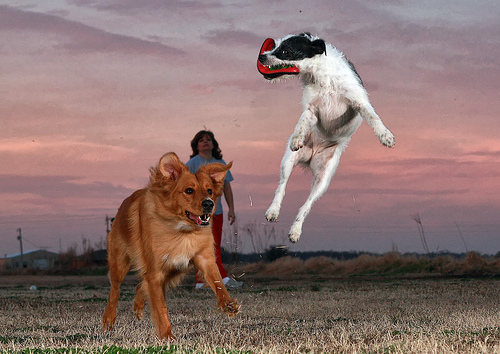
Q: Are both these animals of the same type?
A: Yes, all the animals are dogs.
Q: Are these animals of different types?
A: No, all the animals are dogs.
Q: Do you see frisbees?
A: Yes, there is a frisbee.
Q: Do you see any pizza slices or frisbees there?
A: Yes, there is a frisbee.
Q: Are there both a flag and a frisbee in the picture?
A: No, there is a frisbee but no flags.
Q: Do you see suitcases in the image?
A: No, there are no suitcases.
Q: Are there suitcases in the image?
A: No, there are no suitcases.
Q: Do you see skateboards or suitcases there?
A: No, there are no suitcases or skateboards.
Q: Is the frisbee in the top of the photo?
A: Yes, the frisbee is in the top of the image.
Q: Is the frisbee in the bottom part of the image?
A: No, the frisbee is in the top of the image.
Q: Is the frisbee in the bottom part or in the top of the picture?
A: The frisbee is in the top of the image.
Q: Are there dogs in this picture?
A: Yes, there is a dog.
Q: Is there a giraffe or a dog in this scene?
A: Yes, there is a dog.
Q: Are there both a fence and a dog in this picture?
A: No, there is a dog but no fences.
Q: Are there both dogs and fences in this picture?
A: No, there is a dog but no fences.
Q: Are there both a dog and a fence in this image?
A: No, there is a dog but no fences.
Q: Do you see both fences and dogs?
A: No, there is a dog but no fences.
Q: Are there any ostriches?
A: No, there are no ostriches.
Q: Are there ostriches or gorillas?
A: No, there are no ostriches or gorillas.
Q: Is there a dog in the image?
A: Yes, there is a dog.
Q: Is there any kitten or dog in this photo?
A: Yes, there is a dog.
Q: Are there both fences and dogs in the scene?
A: No, there is a dog but no fences.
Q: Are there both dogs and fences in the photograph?
A: No, there is a dog but no fences.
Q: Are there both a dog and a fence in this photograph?
A: No, there is a dog but no fences.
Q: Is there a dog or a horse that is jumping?
A: Yes, the dog is jumping.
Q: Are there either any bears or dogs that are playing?
A: Yes, the dog is playing.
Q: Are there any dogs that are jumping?
A: Yes, there is a dog that is jumping.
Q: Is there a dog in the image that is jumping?
A: Yes, there is a dog that is jumping.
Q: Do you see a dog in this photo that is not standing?
A: Yes, there is a dog that is jumping .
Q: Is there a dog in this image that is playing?
A: Yes, there is a dog that is playing.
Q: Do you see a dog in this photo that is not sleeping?
A: Yes, there is a dog that is playing .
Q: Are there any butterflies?
A: No, there are no butterflies.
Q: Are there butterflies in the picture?
A: No, there are no butterflies.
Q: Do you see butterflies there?
A: No, there are no butterflies.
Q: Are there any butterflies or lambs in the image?
A: No, there are no butterflies or lambs.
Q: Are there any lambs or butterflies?
A: No, there are no butterflies or lambs.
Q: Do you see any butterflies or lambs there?
A: No, there are no butterflies or lambs.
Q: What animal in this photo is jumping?
A: The animal is a dog.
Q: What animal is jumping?
A: The animal is a dog.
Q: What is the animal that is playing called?
A: The animal is a dog.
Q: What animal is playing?
A: The animal is a dog.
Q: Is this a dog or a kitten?
A: This is a dog.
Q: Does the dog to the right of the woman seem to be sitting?
A: No, the dog is jumping.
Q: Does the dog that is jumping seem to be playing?
A: Yes, the dog is playing.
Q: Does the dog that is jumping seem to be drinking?
A: No, the dog is playing.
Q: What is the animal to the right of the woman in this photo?
A: The animal is a dog.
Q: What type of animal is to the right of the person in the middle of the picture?
A: The animal is a dog.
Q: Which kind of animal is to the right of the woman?
A: The animal is a dog.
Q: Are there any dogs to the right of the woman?
A: Yes, there is a dog to the right of the woman.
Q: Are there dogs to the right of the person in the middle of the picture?
A: Yes, there is a dog to the right of the woman.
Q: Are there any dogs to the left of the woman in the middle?
A: No, the dog is to the right of the woman.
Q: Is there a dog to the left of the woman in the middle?
A: No, the dog is to the right of the woman.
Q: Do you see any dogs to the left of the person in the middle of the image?
A: No, the dog is to the right of the woman.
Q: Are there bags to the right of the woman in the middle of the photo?
A: No, there is a dog to the right of the woman.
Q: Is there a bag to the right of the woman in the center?
A: No, there is a dog to the right of the woman.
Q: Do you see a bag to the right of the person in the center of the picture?
A: No, there is a dog to the right of the woman.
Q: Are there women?
A: Yes, there is a woman.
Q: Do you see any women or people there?
A: Yes, there is a woman.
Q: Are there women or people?
A: Yes, there is a woman.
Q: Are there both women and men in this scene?
A: No, there is a woman but no men.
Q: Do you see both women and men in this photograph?
A: No, there is a woman but no men.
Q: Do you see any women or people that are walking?
A: Yes, the woman is walking.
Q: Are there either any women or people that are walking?
A: Yes, the woman is walking.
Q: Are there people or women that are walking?
A: Yes, the woman is walking.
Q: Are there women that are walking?
A: Yes, there is a woman that is walking.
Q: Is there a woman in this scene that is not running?
A: Yes, there is a woman that is walking.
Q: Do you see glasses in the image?
A: No, there are no glasses.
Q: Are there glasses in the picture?
A: No, there are no glasses.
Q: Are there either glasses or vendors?
A: No, there are no glasses or vendors.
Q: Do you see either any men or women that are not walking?
A: No, there is a woman but she is walking.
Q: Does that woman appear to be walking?
A: Yes, the woman is walking.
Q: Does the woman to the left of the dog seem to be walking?
A: Yes, the woman is walking.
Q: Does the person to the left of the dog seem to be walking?
A: Yes, the woman is walking.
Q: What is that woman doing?
A: The woman is walking.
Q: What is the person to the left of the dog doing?
A: The woman is walking.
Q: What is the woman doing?
A: The woman is walking.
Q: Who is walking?
A: The woman is walking.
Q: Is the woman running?
A: No, the woman is walking.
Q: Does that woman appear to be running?
A: No, the woman is walking.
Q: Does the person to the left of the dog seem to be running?
A: No, the woman is walking.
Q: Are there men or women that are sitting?
A: No, there is a woman but she is walking.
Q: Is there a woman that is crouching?
A: No, there is a woman but she is walking.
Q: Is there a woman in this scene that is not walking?
A: No, there is a woman but she is walking.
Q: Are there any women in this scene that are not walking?
A: No, there is a woman but she is walking.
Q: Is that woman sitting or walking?
A: The woman is walking.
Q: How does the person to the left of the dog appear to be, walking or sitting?
A: The woman is walking.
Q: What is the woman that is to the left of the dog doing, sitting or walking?
A: The woman is walking.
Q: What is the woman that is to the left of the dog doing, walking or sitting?
A: The woman is walking.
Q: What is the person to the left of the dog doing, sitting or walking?
A: The woman is walking.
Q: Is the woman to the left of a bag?
A: No, the woman is to the left of the dog.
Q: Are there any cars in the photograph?
A: No, there are no cars.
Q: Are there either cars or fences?
A: No, there are no cars or fences.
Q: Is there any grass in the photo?
A: Yes, there is grass.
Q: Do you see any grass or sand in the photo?
A: Yes, there is grass.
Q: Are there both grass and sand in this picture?
A: No, there is grass but no sand.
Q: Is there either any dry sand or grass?
A: Yes, there is dry grass.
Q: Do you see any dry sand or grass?
A: Yes, there is dry grass.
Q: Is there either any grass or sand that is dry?
A: Yes, the grass is dry.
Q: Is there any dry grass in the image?
A: Yes, there is dry grass.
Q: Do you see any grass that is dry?
A: Yes, there is grass that is dry.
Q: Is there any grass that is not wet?
A: Yes, there is dry grass.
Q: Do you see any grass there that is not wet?
A: Yes, there is dry grass.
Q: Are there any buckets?
A: No, there are no buckets.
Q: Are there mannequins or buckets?
A: No, there are no buckets or mannequins.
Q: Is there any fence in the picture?
A: No, there are no fences.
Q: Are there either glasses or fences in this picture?
A: No, there are no fences or glasses.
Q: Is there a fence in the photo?
A: No, there are no fences.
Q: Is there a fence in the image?
A: No, there are no fences.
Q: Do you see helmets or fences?
A: No, there are no fences or helmets.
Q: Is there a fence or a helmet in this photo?
A: No, there are no fences or helmets.